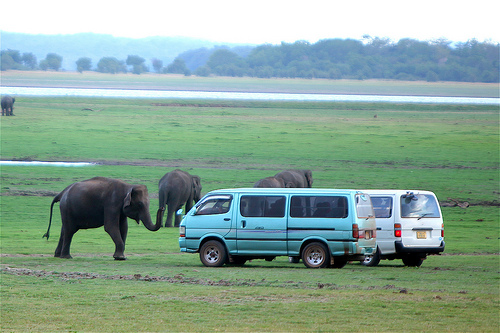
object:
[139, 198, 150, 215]
nose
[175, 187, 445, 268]
van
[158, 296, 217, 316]
grass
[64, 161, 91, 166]
water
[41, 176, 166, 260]
elephant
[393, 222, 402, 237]
light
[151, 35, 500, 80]
tree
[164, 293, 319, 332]
ground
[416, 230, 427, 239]
plate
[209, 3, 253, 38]
sky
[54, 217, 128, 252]
leg